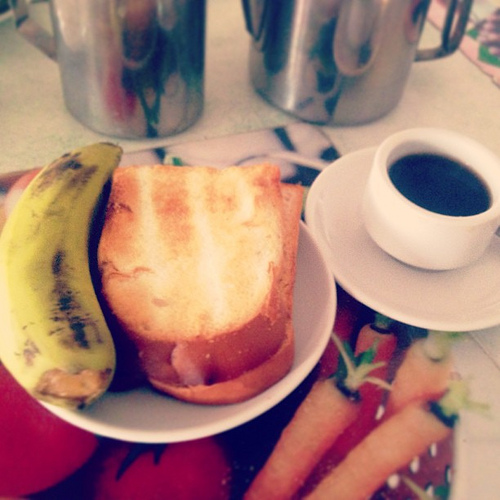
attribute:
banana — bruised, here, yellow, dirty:
[1, 139, 122, 414]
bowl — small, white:
[35, 214, 338, 448]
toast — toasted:
[94, 162, 289, 386]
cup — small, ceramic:
[362, 125, 499, 273]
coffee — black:
[388, 149, 495, 217]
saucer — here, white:
[300, 145, 499, 335]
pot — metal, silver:
[239, 0, 473, 129]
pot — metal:
[8, 1, 209, 142]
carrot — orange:
[299, 375, 491, 499]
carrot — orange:
[241, 332, 394, 500]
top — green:
[332, 333, 395, 394]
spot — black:
[47, 248, 101, 351]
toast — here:
[145, 180, 303, 406]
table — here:
[3, 0, 500, 377]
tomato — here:
[0, 361, 99, 496]